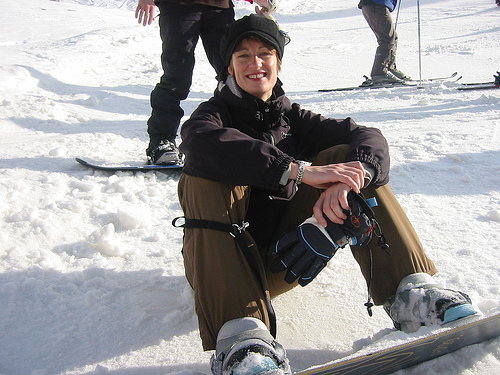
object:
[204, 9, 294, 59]
hat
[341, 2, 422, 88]
person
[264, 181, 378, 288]
gloves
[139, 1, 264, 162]
pants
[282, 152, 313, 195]
watch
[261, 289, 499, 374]
board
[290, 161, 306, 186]
wrist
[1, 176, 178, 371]
snow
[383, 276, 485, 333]
feet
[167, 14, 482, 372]
woman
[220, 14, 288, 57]
cap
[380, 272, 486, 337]
boots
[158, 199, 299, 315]
strap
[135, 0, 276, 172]
person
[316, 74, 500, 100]
snowboarder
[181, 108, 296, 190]
sleeve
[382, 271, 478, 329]
shoe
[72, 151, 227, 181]
snowboard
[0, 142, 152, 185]
shadow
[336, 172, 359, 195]
fingers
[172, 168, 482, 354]
pants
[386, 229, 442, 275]
wrinkles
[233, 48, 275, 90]
face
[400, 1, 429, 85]
poles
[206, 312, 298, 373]
boot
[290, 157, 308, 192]
bracelet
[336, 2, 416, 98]
pants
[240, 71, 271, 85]
mouth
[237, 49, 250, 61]
eyes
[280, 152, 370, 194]
hand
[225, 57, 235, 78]
ear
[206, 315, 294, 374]
foot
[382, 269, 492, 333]
foot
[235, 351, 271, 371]
snow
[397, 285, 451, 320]
snow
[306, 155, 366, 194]
hand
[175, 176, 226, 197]
knee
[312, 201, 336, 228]
fingers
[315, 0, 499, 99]
skier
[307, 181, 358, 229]
hand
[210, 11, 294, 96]
head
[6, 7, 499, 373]
ground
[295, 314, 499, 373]
snowboard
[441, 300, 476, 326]
tip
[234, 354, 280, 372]
tip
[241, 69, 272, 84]
grin